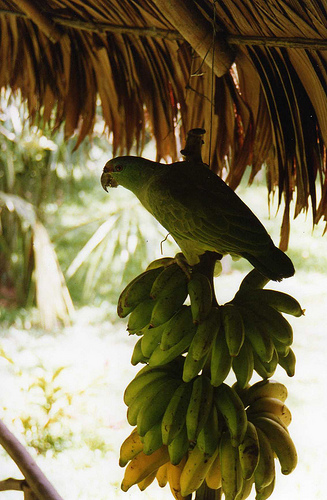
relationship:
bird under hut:
[101, 152, 295, 282] [1, 1, 316, 254]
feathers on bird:
[140, 161, 295, 282] [101, 152, 295, 282]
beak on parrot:
[97, 178, 125, 190] [90, 143, 287, 259]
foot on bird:
[164, 253, 191, 279] [101, 152, 295, 282]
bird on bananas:
[101, 152, 295, 282] [116, 240, 303, 499]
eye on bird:
[115, 162, 123, 173] [101, 152, 295, 282]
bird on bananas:
[101, 152, 295, 282] [97, 253, 310, 497]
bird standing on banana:
[99, 152, 297, 278] [147, 263, 181, 298]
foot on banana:
[165, 251, 207, 284] [184, 264, 214, 324]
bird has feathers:
[101, 152, 295, 282] [140, 175, 297, 277]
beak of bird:
[100, 178, 109, 193] [99, 152, 297, 278]